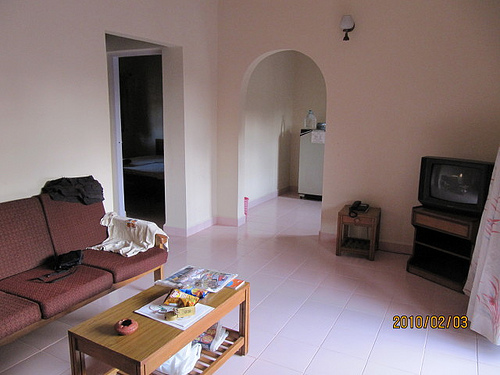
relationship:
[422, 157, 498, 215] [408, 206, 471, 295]
tv on stand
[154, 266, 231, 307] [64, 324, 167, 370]
newspaper on coffee table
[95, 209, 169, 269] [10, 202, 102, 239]
shirt on couch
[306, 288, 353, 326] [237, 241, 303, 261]
tile on floor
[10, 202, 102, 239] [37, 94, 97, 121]
couch by wall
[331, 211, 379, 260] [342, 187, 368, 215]
small table with telephone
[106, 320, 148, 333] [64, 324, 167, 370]
ashtray on coffee table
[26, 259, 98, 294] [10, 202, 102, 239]
purse on couch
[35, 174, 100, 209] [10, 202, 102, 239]
pants on couch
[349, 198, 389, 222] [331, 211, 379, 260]
phone on small table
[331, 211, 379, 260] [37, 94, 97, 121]
small table by wall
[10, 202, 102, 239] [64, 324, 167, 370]
couch behind coffee table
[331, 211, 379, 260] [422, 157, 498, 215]
small table by tv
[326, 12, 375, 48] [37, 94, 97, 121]
light on wall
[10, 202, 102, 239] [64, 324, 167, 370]
couch by coffee table